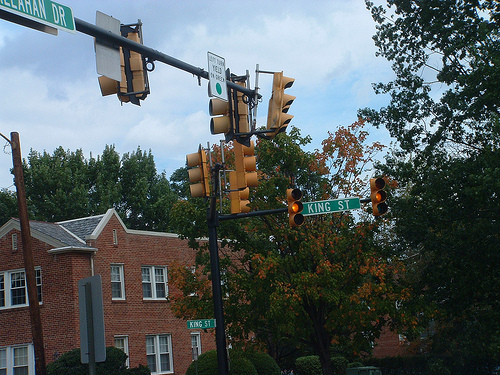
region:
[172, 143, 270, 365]
several traffic lights on a pole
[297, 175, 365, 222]
a green and white street sign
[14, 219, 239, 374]
a two story brick building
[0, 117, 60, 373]
a wooden electrical pole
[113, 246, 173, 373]
four windows in a building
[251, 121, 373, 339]
a tree with red and green leaves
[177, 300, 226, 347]
a street sign attached to a pole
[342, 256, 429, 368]
a brick building behind trees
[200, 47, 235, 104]
a traffic sign with writing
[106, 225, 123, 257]
a small vent window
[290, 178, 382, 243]
a sign that says king st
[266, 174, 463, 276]
two yellow stoplights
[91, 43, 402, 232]
multiple stop lights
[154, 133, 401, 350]
two signs that say king st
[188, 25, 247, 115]
a yield sign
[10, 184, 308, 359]
a red brick building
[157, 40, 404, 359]
a tree behind some stop signs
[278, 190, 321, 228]
a stop sign with a yellow light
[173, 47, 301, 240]
stop signs hanging on a post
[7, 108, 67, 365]
a brown pole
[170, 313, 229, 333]
green and white street sign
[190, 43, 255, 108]
large square white sign across street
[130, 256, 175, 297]
large white window in building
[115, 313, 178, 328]
red bricks on wall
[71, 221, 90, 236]
gray slant on roof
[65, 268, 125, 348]
gray back of street sign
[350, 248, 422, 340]
colorful colors on tree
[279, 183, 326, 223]
yellow street light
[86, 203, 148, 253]
triangle edge of roof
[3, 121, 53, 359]
large brown post on side walk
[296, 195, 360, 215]
street sign for king street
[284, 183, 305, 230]
stoplight lit up yellow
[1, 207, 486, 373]
building made of red brick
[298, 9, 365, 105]
blue cloudy sky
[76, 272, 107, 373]
back of street sign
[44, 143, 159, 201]
trees with green leaves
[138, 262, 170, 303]
window with white frame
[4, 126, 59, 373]
pole for street light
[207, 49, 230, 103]
sign that says left turn yield on green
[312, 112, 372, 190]
brown leaves on tree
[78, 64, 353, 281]
Street intersection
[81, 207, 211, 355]
Brick building on the corner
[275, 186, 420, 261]
King street sign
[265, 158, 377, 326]
Traffic light with yellow light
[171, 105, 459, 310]
Traffic lights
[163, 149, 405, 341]
Tree's leaves are changing color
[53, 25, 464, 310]
Street intersection on a fall day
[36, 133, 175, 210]
Trees behind the brick building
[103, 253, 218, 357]
Windows on the brick building